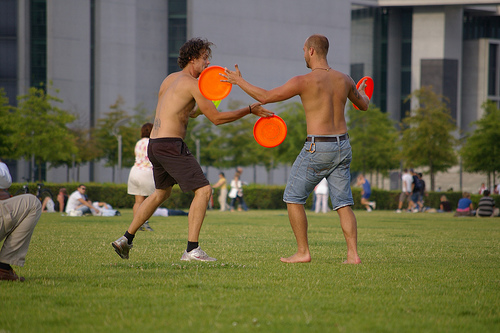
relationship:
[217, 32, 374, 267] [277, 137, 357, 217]
man wearing shorts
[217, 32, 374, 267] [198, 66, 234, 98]
man holding frisbee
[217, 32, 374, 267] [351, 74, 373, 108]
man holding frisbee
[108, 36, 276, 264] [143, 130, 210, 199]
man wearing shorts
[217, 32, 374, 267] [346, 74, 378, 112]
man holding frisbees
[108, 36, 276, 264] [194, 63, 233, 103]
man holding frisbee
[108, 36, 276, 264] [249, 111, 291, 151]
man holding frisbee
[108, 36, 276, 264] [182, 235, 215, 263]
man has shoes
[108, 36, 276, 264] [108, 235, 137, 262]
man has tennis shoes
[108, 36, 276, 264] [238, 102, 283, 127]
man has hand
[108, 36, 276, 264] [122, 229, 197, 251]
man wears socks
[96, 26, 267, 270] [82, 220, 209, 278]
man wears tennis shoes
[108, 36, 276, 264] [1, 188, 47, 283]
man wears pants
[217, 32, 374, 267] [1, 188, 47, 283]
man wears pants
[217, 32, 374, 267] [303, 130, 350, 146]
man wears dark belt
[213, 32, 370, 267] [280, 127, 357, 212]
man wears shorts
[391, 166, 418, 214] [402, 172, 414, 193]
person wears white shirt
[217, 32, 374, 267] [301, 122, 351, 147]
man wears black belt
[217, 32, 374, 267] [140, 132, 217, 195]
man wears shorts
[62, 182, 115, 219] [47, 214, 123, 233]
man on grass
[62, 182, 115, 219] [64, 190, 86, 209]
man wears shirt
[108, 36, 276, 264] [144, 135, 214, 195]
man wears shorts